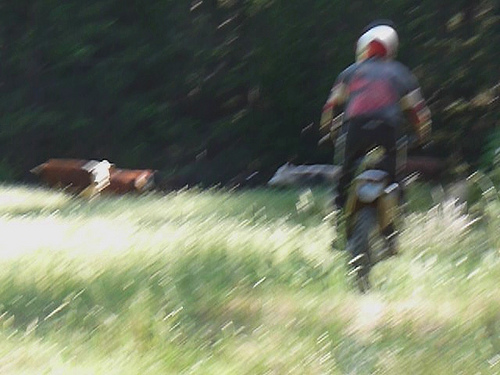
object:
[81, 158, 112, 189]
head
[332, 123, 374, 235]
leg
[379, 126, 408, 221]
leg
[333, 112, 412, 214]
jeans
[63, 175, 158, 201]
red truck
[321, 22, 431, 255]
boy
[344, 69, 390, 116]
number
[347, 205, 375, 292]
tire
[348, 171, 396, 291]
bike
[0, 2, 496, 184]
trees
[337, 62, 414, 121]
gray shirt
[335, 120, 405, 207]
pants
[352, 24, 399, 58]
helmet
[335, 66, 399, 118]
design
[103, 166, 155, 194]
cow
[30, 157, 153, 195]
cow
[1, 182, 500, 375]
grass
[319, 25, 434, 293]
person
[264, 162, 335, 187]
animal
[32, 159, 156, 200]
object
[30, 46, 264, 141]
wall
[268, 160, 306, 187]
head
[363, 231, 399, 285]
prongs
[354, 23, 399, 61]
head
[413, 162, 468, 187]
roadway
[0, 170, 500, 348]
field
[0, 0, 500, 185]
background